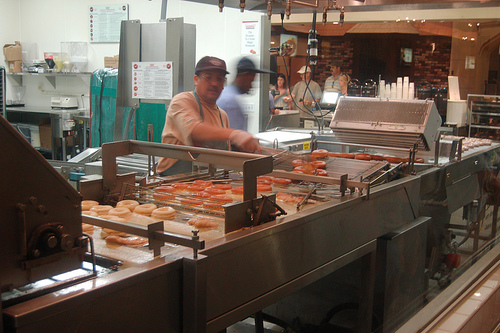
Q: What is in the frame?
A: A large amount of doughnuts.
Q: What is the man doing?
A: Making doughnuts.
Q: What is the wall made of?
A: Brick.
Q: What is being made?
A: Donuts.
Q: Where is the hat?
A: On the man's head.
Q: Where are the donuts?
A: On a conveyor belt.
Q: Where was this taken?
A: In a donut shop.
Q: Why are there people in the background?
A: They are waiting to be served.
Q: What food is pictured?
A: Doughnuts.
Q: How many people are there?
A: Five.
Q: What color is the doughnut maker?
A: Silver.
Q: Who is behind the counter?
A: The workers.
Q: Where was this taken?
A: In a bakery.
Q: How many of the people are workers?
A: Two.